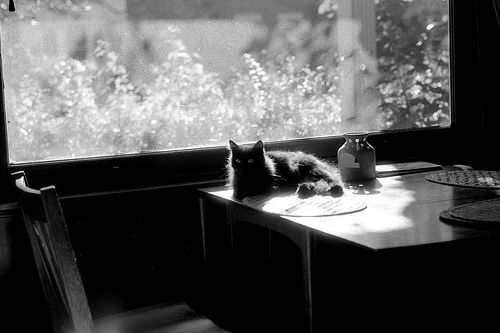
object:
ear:
[229, 140, 240, 151]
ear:
[253, 139, 262, 147]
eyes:
[247, 151, 260, 161]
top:
[192, 160, 497, 252]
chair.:
[7, 171, 222, 333]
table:
[195, 160, 498, 333]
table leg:
[301, 226, 313, 333]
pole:
[335, 4, 378, 136]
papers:
[369, 160, 441, 179]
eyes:
[232, 154, 244, 164]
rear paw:
[327, 169, 344, 195]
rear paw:
[292, 181, 315, 199]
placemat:
[242, 187, 368, 217]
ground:
[410, 82, 453, 125]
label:
[338, 150, 360, 170]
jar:
[334, 133, 376, 184]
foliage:
[1, 27, 341, 158]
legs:
[230, 183, 248, 202]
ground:
[368, 182, 431, 231]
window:
[4, 0, 451, 167]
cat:
[223, 139, 341, 199]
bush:
[3, 0, 342, 165]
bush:
[375, 0, 451, 127]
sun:
[0, 14, 416, 236]